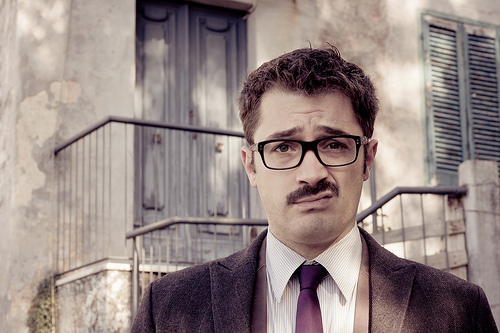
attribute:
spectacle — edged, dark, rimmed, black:
[246, 135, 368, 170]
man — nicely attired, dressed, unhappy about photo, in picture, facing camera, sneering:
[134, 49, 497, 328]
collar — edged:
[263, 229, 362, 303]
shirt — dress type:
[264, 226, 362, 331]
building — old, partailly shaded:
[8, 5, 495, 327]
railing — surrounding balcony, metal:
[54, 116, 269, 281]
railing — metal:
[358, 184, 468, 282]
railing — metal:
[125, 214, 266, 317]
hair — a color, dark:
[238, 48, 378, 144]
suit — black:
[249, 229, 370, 329]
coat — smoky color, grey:
[131, 226, 497, 329]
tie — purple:
[289, 263, 329, 330]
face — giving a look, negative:
[256, 120, 365, 244]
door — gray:
[133, 4, 250, 264]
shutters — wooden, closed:
[420, 12, 497, 188]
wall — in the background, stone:
[5, 4, 133, 330]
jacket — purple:
[253, 228, 369, 328]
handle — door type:
[151, 131, 163, 145]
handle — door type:
[215, 142, 227, 154]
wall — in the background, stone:
[248, 5, 496, 258]